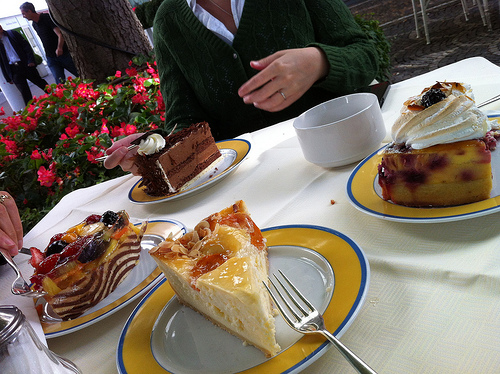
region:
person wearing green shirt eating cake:
[154, 3, 373, 167]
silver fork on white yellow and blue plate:
[262, 267, 338, 358]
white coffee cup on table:
[294, 87, 386, 177]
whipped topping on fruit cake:
[382, 77, 489, 202]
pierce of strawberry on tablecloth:
[326, 194, 340, 209]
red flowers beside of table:
[32, 88, 103, 174]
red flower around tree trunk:
[48, 32, 150, 136]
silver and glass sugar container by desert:
[0, 304, 83, 371]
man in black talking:
[19, 3, 70, 86]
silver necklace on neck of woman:
[178, 1, 233, 30]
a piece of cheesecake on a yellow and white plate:
[153, 204, 333, 372]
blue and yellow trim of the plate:
[309, 242, 385, 307]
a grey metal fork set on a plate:
[259, 268, 381, 371]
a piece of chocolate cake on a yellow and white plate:
[121, 125, 241, 195]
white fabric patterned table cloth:
[386, 268, 498, 368]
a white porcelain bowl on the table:
[286, 99, 395, 168]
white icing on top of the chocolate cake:
[133, 129, 176, 165]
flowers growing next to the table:
[11, 73, 146, 185]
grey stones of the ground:
[417, 29, 480, 59]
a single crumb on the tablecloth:
[326, 195, 340, 209]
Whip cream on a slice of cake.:
[135, 130, 165, 157]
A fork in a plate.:
[259, 267, 380, 372]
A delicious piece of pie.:
[146, 196, 281, 361]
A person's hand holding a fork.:
[1, 185, 26, 260]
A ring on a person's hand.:
[0, 191, 13, 203]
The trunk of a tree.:
[44, 0, 153, 89]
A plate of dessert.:
[343, 77, 498, 226]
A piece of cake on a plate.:
[121, 116, 253, 206]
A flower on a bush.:
[34, 159, 60, 189]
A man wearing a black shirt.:
[16, 2, 81, 84]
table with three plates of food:
[10, 49, 498, 369]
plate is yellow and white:
[83, 195, 390, 372]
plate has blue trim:
[92, 198, 379, 372]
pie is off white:
[135, 200, 313, 362]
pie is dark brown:
[113, 118, 232, 191]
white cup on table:
[268, 80, 393, 182]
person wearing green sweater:
[125, 4, 395, 157]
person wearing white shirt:
[174, 0, 268, 40]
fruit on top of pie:
[30, 209, 148, 324]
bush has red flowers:
[15, 78, 179, 192]